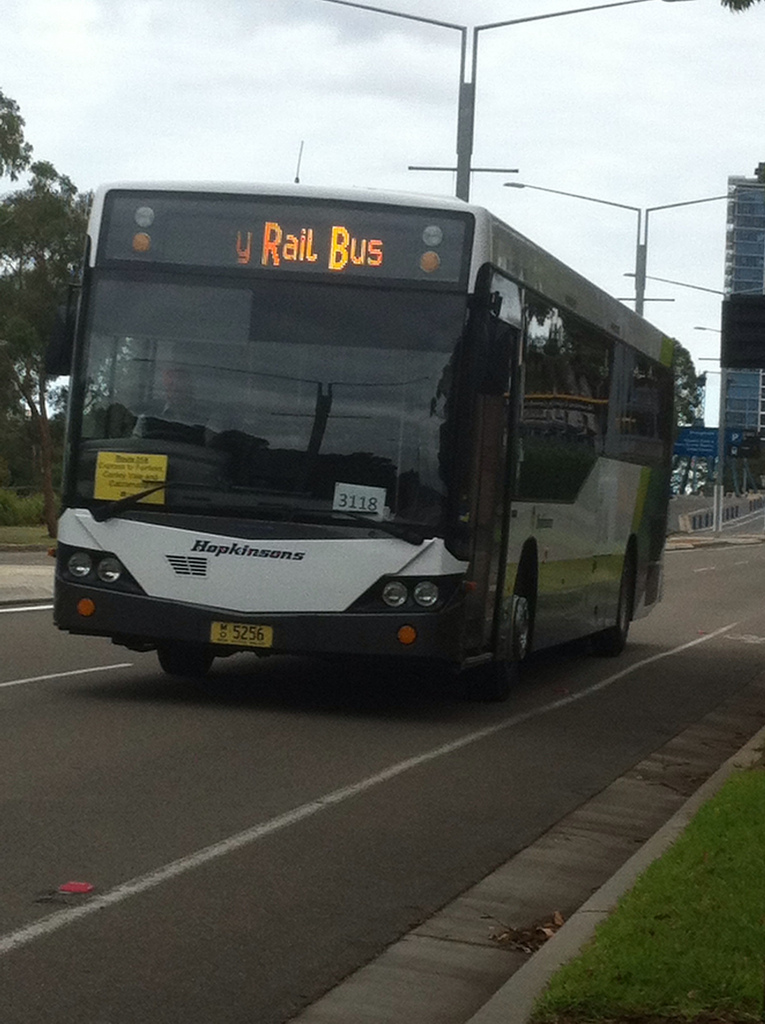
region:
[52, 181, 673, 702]
A gray bus driving on the road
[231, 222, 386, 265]
The lit words on the front display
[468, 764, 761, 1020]
The sidewalk with green lawn on it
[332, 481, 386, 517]
The number displayed on the bus front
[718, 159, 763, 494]
A multi-storied tall building in the background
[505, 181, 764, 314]
One of the street lights and its pole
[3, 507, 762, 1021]
The cemented surface of the road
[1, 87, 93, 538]
Some trees on the far side of the raod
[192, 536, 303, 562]
The name of the bus manufacturer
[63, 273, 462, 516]
The huge glass front of the bus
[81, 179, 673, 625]
white and green city bus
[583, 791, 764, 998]
short green grass by road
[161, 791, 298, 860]
painted white line on road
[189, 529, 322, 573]
black logo on city bus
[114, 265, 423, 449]
front windshield of city bus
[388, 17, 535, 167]
winged street light over road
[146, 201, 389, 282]
digital display on bus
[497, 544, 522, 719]
black rubber bus tire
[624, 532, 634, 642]
black rubber bus tire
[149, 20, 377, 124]
thick white clouds in sky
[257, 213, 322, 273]
a signage with the word rail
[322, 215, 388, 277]
a sign with the word bus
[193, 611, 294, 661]
a license plate on a vehicle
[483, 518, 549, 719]
the front wheel of a bus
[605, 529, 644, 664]
the rear wheel of a bus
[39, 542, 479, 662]
the headlights of a vehicle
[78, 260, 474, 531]
the wind shield of a bus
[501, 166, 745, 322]
a light post on the street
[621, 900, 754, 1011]
a patch of grass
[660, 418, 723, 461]
a street sign on a post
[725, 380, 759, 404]
A window on a building.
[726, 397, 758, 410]
A window on a building.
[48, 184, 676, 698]
a bus on the street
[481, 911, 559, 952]
a pile of leaves in the gutter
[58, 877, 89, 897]
a smashed piece of garbage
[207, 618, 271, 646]
a liscense plate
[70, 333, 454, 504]
a windshield on a bus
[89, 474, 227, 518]
a windshield wiper on a bus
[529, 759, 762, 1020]
grass near the curb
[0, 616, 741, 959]
white marking in the street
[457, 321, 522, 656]
a door on a bus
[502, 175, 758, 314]
a street light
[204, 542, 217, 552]
black letter on bus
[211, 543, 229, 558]
black letter on bus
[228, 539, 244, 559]
black letter on bus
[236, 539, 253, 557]
black letter on bus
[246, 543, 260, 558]
black letter on bus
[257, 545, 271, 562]
black letter on bus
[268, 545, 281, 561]
black letter on bus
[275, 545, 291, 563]
black letter on bus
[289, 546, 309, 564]
black letter on bus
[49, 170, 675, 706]
a bus on a street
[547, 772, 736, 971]
a concrete curb next to a street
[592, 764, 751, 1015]
a patch of green grass next to curb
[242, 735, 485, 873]
a white line painted on street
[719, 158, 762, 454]
a tall building with windows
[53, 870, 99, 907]
a red reflector on a street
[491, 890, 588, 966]
brown leaves on the ground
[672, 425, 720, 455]
a blue and white street sign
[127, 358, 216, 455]
a person driving a bus